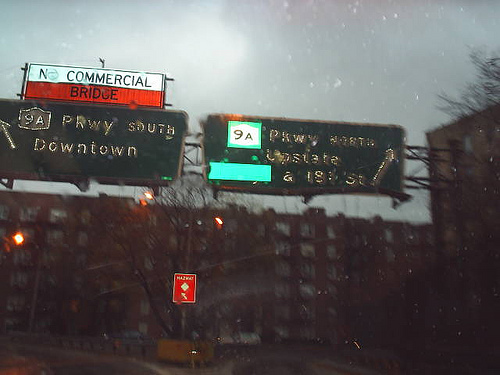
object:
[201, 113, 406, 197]
sign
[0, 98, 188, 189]
sign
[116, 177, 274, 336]
tree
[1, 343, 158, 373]
road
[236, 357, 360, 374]
road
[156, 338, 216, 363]
bumper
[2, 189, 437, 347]
housing unit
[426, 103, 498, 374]
housing unit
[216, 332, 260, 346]
car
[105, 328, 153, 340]
car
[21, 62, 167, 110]
sign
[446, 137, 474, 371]
post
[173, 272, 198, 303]
sign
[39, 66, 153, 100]
writing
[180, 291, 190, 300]
arrow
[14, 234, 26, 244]
light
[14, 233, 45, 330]
pole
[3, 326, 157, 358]
railing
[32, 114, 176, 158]
letters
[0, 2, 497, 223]
sky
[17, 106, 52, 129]
writing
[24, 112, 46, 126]
9a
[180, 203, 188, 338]
pole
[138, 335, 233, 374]
corner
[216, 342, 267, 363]
railing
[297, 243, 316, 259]
window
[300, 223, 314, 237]
window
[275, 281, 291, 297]
window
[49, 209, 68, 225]
window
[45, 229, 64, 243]
window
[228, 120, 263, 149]
patch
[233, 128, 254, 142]
text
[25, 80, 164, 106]
orange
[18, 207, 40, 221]
window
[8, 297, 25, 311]
window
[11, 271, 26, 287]
window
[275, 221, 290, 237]
window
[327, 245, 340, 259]
window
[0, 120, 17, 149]
arrow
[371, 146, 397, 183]
arrow